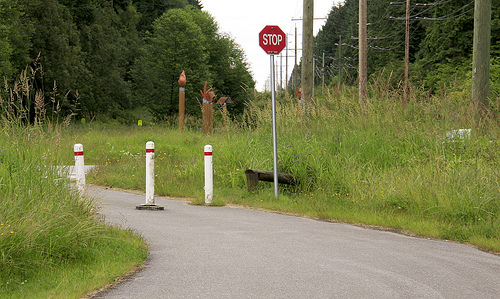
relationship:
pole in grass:
[465, 5, 495, 142] [339, 94, 442, 197]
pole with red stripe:
[199, 141, 212, 203] [203, 151, 212, 156]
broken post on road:
[238, 167, 301, 194] [49, 164, 499, 297]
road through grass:
[49, 164, 499, 297] [87, 64, 499, 256]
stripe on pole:
[74, 147, 82, 156] [69, 139, 89, 201]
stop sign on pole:
[255, 19, 295, 66] [263, 52, 287, 201]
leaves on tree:
[49, 54, 139, 107] [132, 10, 214, 113]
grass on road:
[0, 62, 500, 296] [90, 180, 499, 297]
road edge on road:
[79, 215, 151, 297] [49, 164, 499, 297]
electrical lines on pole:
[250, 0, 465, 70] [301, 0, 312, 110]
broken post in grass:
[244, 167, 296, 190] [70, 91, 498, 245]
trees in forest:
[0, 4, 254, 111] [0, 1, 495, 250]